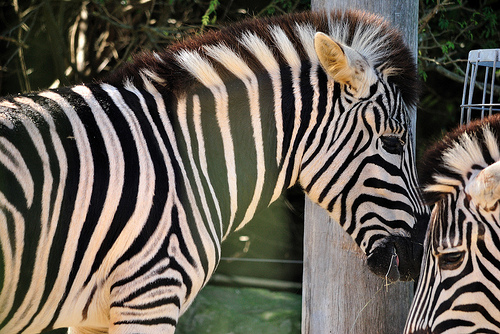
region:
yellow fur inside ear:
[308, 36, 367, 108]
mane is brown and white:
[423, 126, 499, 178]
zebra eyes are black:
[370, 123, 405, 173]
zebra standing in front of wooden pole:
[308, 5, 413, 332]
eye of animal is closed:
[436, 238, 465, 293]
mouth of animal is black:
[376, 236, 422, 292]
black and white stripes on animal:
[0, 86, 428, 326]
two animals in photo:
[1, 96, 498, 332]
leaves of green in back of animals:
[11, 0, 203, 49]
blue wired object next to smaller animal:
[454, 55, 498, 107]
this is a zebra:
[0, 4, 440, 329]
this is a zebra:
[404, 105, 495, 325]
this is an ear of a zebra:
[295, 10, 379, 108]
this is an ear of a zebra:
[459, 161, 497, 207]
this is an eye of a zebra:
[434, 242, 471, 279]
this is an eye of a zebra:
[376, 120, 422, 171]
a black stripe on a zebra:
[114, 73, 179, 302]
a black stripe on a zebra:
[52, 86, 95, 331]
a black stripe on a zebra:
[136, 58, 219, 266]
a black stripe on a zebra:
[256, 15, 318, 195]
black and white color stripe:
[26, 104, 131, 257]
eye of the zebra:
[380, 133, 403, 151]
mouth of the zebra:
[370, 240, 420, 272]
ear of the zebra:
[314, 30, 368, 80]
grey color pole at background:
[304, 240, 356, 332]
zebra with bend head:
[421, 197, 498, 329]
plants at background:
[11, 6, 111, 58]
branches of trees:
[433, 57, 463, 86]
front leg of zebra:
[103, 287, 180, 332]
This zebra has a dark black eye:
[379, 125, 406, 163]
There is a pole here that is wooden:
[316, 263, 342, 323]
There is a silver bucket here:
[472, 49, 488, 90]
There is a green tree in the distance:
[73, 14, 91, 41]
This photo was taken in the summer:
[98, 38, 333, 290]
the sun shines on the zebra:
[31, 38, 390, 276]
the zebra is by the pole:
[227, 6, 490, 238]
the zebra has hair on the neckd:
[112, 26, 395, 73]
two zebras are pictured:
[18, 36, 498, 281]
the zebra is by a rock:
[205, 262, 250, 321]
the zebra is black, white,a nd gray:
[51, 123, 353, 331]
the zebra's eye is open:
[332, 78, 466, 231]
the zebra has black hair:
[382, 43, 452, 143]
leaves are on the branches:
[2, 17, 291, 137]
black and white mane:
[118, 16, 390, 115]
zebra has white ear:
[311, 27, 414, 119]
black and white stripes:
[38, 107, 429, 239]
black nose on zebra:
[343, 226, 446, 303]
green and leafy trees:
[8, 16, 264, 43]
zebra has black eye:
[369, 118, 406, 169]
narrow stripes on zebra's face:
[294, 114, 425, 261]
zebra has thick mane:
[149, 14, 264, 115]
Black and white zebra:
[399, 112, 499, 332]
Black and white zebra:
[0, 9, 432, 331]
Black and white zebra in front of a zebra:
[0, 7, 429, 332]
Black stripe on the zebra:
[219, 25, 279, 215]